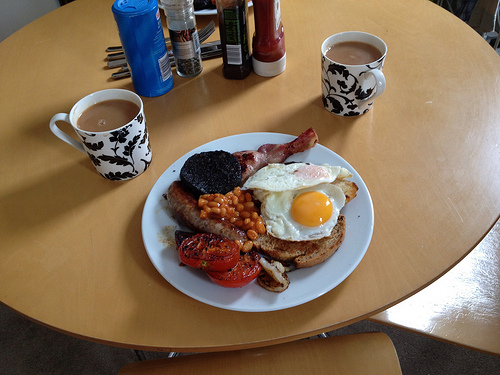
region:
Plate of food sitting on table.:
[138, 123, 375, 315]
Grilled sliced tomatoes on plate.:
[177, 232, 260, 288]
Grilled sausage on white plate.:
[167, 181, 252, 246]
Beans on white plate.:
[203, 188, 266, 238]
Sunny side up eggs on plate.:
[265, 166, 347, 245]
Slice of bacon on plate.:
[239, 123, 331, 173]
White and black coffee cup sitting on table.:
[51, 66, 160, 186]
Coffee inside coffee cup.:
[76, 93, 142, 132]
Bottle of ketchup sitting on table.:
[253, 3, 297, 76]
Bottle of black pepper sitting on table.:
[163, 5, 202, 82]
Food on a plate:
[152, 127, 399, 316]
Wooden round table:
[45, 200, 142, 338]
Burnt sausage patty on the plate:
[170, 142, 265, 210]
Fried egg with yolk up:
[269, 176, 356, 257]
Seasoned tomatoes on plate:
[173, 228, 263, 295]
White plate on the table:
[284, 265, 339, 309]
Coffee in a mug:
[315, 26, 409, 129]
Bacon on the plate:
[216, 114, 345, 188]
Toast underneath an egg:
[262, 210, 392, 324]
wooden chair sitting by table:
[403, 279, 496, 356]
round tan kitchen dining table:
[20, 200, 130, 350]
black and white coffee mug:
[46, 74, 155, 181]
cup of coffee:
[313, 19, 393, 129]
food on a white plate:
[136, 125, 385, 326]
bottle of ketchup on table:
[248, 8, 295, 88]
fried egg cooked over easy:
[248, 162, 350, 244]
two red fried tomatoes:
[176, 227, 266, 297]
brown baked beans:
[193, 185, 271, 250]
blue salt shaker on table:
[110, 3, 179, 102]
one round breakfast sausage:
[176, 142, 253, 204]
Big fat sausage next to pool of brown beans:
[168, 178, 251, 248]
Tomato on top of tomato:
[180, 232, 240, 273]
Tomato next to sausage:
[176, 231, 240, 271]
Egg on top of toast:
[260, 180, 348, 240]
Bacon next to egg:
[213, 126, 323, 178]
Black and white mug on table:
[41, 88, 153, 183]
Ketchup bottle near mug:
[247, 0, 287, 78]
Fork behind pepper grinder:
[102, 23, 215, 54]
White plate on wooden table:
[139, 130, 376, 314]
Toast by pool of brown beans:
[255, 205, 353, 268]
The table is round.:
[7, 5, 494, 363]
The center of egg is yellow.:
[260, 191, 345, 239]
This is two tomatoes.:
[185, 232, 255, 287]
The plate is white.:
[162, 124, 391, 319]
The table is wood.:
[11, 4, 491, 344]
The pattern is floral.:
[320, 22, 389, 124]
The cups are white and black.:
[51, 90, 185, 193]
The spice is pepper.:
[161, 2, 209, 78]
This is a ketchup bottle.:
[253, 2, 285, 79]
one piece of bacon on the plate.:
[254, 127, 323, 172]